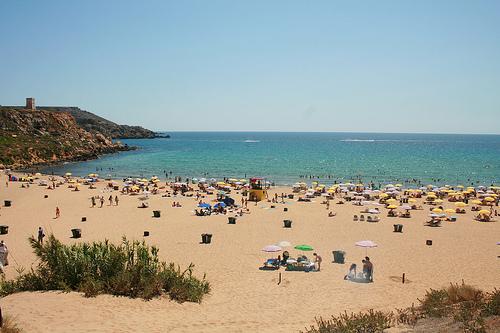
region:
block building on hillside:
[15, 84, 68, 133]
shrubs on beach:
[22, 229, 212, 316]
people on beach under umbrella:
[260, 235, 324, 282]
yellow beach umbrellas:
[379, 191, 469, 228]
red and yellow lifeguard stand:
[242, 173, 280, 214]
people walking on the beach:
[83, 191, 132, 213]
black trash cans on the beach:
[195, 216, 298, 249]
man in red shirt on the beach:
[50, 195, 69, 222]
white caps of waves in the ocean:
[335, 134, 439, 156]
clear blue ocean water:
[85, 98, 490, 212]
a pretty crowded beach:
[36, 167, 498, 249]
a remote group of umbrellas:
[248, 239, 324, 274]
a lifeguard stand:
[242, 169, 269, 212]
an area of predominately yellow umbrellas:
[379, 180, 498, 244]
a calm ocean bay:
[15, 140, 498, 190]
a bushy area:
[2, 231, 216, 306]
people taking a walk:
[81, 190, 122, 211]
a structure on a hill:
[15, 88, 52, 119]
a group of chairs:
[339, 211, 383, 225]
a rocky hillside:
[6, 100, 176, 168]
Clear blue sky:
[120, 25, 429, 85]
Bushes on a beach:
[17, 238, 202, 297]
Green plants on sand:
[28, 228, 300, 310]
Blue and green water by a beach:
[179, 131, 404, 188]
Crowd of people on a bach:
[51, 172, 266, 229]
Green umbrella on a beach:
[292, 236, 314, 288]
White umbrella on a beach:
[343, 233, 410, 296]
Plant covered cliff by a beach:
[11, 95, 142, 177]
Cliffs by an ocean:
[8, 96, 241, 195]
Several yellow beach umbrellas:
[370, 175, 495, 225]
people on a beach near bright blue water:
[61, 111, 455, 241]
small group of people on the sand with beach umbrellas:
[255, 230, 325, 283]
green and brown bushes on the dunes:
[38, 234, 219, 310]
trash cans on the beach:
[185, 224, 222, 260]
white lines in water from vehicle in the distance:
[209, 126, 441, 160]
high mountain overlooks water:
[5, 65, 186, 163]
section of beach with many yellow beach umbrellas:
[290, 176, 494, 227]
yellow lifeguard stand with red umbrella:
[235, 165, 281, 215]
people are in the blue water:
[274, 164, 471, 190]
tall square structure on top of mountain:
[15, 83, 62, 120]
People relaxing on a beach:
[41, 135, 428, 291]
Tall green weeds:
[13, 234, 200, 320]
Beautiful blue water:
[173, 133, 396, 209]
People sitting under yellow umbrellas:
[405, 185, 495, 212]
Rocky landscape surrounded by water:
[9, 93, 180, 167]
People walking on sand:
[83, 191, 123, 210]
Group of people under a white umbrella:
[324, 235, 376, 282]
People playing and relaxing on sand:
[36, 140, 496, 299]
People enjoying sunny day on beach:
[10, 52, 499, 315]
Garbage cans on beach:
[198, 223, 218, 251]